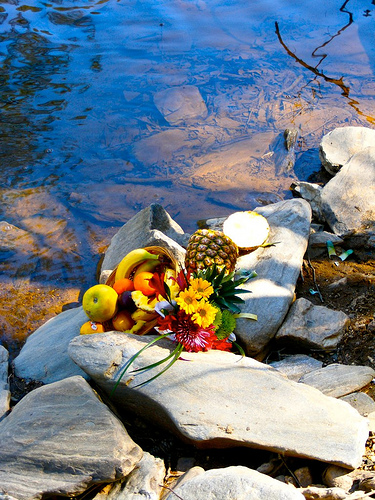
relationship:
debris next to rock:
[323, 236, 337, 259] [275, 295, 351, 355]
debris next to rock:
[323, 236, 337, 259] [202, 196, 312, 358]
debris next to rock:
[336, 247, 354, 262] [306, 227, 345, 258]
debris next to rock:
[331, 258, 340, 270] [202, 196, 312, 358]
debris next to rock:
[307, 286, 319, 296] [275, 295, 351, 355]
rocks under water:
[151, 83, 208, 124] [0, 1, 362, 372]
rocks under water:
[283, 106, 351, 153] [0, 1, 362, 372]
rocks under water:
[176, 129, 299, 196] [0, 1, 362, 372]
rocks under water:
[62, 180, 186, 225] [0, 1, 362, 372]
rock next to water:
[7, 299, 86, 385] [13, 24, 244, 215]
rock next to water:
[315, 122, 362, 176] [13, 24, 244, 215]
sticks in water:
[226, 73, 295, 143] [0, 1, 362, 372]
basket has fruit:
[103, 242, 183, 336] [79, 281, 120, 324]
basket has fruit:
[103, 242, 183, 336] [113, 244, 162, 285]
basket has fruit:
[103, 242, 183, 336] [131, 268, 160, 296]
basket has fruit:
[103, 242, 183, 336] [111, 277, 134, 295]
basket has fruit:
[103, 242, 183, 336] [78, 317, 105, 335]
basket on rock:
[103, 242, 183, 336] [99, 199, 189, 279]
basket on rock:
[103, 242, 183, 336] [188, 192, 318, 357]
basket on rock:
[103, 242, 183, 336] [8, 304, 98, 385]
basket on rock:
[103, 242, 183, 336] [0, 371, 143, 498]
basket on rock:
[103, 242, 183, 336] [165, 462, 311, 498]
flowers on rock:
[141, 253, 255, 379] [188, 192, 318, 357]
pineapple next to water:
[184, 228, 239, 293] [0, 1, 362, 372]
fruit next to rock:
[81, 212, 269, 352] [188, 192, 318, 357]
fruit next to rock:
[81, 212, 269, 352] [97, 199, 191, 292]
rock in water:
[149, 84, 214, 126] [5, 4, 332, 182]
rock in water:
[145, 60, 193, 80] [5, 4, 332, 182]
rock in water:
[130, 133, 206, 168] [5, 4, 332, 182]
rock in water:
[190, 153, 285, 192] [5, 4, 332, 182]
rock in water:
[273, 97, 335, 128] [5, 4, 332, 182]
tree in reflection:
[8, 31, 79, 183] [1, 0, 105, 186]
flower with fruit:
[184, 296, 220, 330] [44, 229, 160, 341]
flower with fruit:
[170, 286, 202, 320] [44, 229, 160, 341]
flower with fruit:
[183, 271, 217, 299] [44, 229, 160, 341]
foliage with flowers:
[108, 332, 182, 401] [142, 268, 236, 353]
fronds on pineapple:
[194, 259, 253, 313] [184, 228, 239, 276]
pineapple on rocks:
[166, 226, 238, 286] [165, 108, 365, 277]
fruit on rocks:
[79, 209, 269, 347] [0, 117, 371, 494]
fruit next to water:
[79, 209, 269, 347] [13, 28, 272, 173]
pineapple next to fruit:
[184, 228, 239, 293] [75, 282, 124, 323]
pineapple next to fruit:
[184, 228, 239, 293] [109, 244, 164, 282]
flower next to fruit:
[174, 288, 202, 314] [82, 284, 120, 320]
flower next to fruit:
[193, 301, 216, 326] [82, 284, 120, 320]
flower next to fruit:
[173, 312, 215, 351] [116, 289, 137, 314]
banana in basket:
[114, 249, 148, 286] [103, 244, 187, 332]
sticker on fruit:
[90, 320, 97, 330] [79, 209, 270, 338]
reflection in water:
[305, 17, 354, 77] [265, 37, 358, 119]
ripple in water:
[3, 2, 187, 194] [0, 0, 373, 410]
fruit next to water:
[79, 209, 269, 347] [20, 6, 355, 273]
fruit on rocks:
[79, 209, 269, 347] [0, 55, 373, 498]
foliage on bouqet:
[106, 330, 182, 390] [154, 274, 235, 352]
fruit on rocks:
[81, 212, 269, 352] [10, 265, 330, 479]